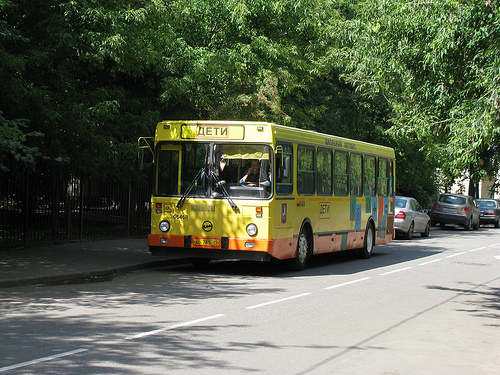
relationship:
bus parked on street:
[136, 120, 396, 269] [1, 225, 499, 374]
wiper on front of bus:
[211, 172, 238, 212] [136, 120, 396, 269]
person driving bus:
[240, 162, 270, 188] [136, 120, 396, 269]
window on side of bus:
[317, 149, 333, 194] [136, 120, 396, 269]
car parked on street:
[396, 195, 431, 238] [1, 225, 499, 374]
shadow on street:
[0, 314, 388, 374] [1, 225, 499, 374]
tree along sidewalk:
[41, 0, 157, 161] [0, 235, 179, 286]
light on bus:
[246, 223, 257, 237] [136, 120, 396, 269]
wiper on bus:
[211, 172, 238, 212] [136, 120, 396, 269]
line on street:
[126, 313, 225, 340] [1, 225, 499, 374]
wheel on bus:
[289, 229, 310, 271] [136, 120, 396, 269]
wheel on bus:
[363, 221, 374, 257] [136, 120, 396, 269]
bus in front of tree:
[136, 120, 396, 269] [41, 0, 157, 161]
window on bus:
[317, 149, 333, 194] [136, 120, 396, 269]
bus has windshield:
[136, 120, 396, 269] [212, 145, 273, 200]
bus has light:
[136, 120, 396, 269] [246, 223, 257, 237]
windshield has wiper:
[212, 145, 273, 200] [211, 172, 238, 212]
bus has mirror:
[136, 120, 396, 269] [280, 155, 291, 179]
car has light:
[396, 195, 431, 238] [395, 210, 406, 220]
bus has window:
[136, 120, 396, 269] [317, 149, 333, 194]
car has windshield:
[396, 195, 431, 238] [395, 199, 408, 209]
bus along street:
[136, 120, 396, 269] [1, 225, 499, 374]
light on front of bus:
[246, 223, 257, 237] [136, 120, 396, 269]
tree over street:
[41, 0, 157, 161] [1, 225, 499, 374]